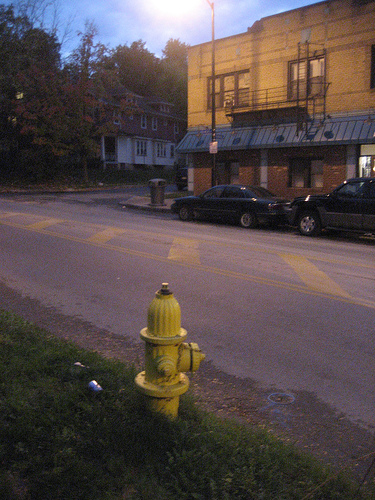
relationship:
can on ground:
[83, 377, 116, 402] [1, 315, 366, 495]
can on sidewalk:
[146, 178, 166, 210] [131, 199, 179, 211]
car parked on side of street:
[170, 178, 291, 231] [125, 182, 370, 247]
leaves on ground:
[40, 313, 369, 477] [1, 171, 374, 497]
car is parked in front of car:
[170, 178, 299, 231] [288, 178, 374, 236]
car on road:
[170, 178, 299, 231] [7, 196, 373, 417]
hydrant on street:
[126, 275, 207, 425] [9, 211, 358, 354]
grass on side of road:
[2, 309, 373, 497] [0, 196, 371, 476]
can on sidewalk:
[148, 178, 166, 210] [118, 184, 177, 216]